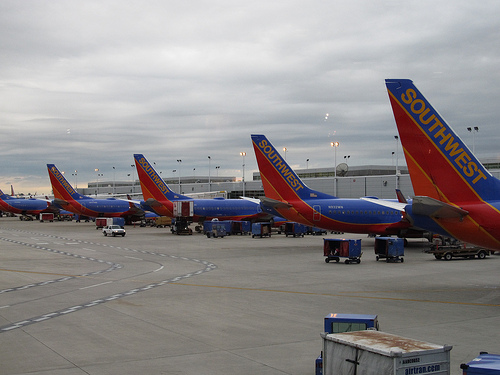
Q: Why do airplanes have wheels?
A: To roll.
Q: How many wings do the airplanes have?
A: Two.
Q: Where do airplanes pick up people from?
A: Airport.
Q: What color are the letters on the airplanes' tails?
A: Yellow.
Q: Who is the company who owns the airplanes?
A: Southwest.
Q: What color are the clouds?
A: White.